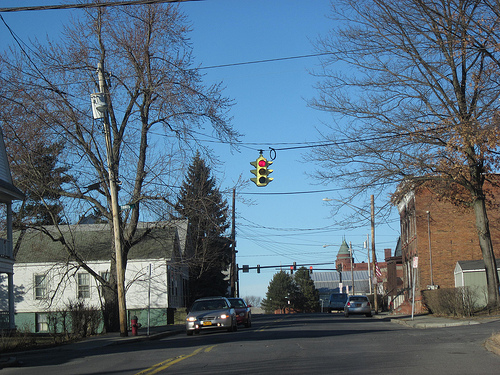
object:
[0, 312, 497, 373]
concrete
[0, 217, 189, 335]
house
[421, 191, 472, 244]
wall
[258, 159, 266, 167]
light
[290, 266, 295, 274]
traffic light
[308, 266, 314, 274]
traffic light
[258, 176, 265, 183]
light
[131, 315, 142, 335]
hydrant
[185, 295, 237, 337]
car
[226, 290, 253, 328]
car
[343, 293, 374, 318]
car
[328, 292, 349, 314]
car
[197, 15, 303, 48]
sky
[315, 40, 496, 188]
leaves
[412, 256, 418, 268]
sign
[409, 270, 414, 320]
stick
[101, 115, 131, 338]
pole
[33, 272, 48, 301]
windows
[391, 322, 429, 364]
ground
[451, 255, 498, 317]
shed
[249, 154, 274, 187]
light box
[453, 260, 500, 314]
building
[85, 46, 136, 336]
power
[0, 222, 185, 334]
building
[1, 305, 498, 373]
street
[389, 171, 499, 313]
building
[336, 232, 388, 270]
building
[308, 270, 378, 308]
building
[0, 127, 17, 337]
building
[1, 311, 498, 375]
road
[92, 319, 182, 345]
sidewalk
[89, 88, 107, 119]
transfomer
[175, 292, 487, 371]
intersection